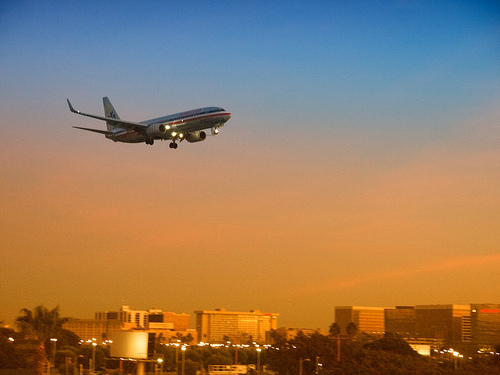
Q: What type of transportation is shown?
A: Airplane.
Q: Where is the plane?
A: In the sky.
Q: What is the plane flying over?
A: A city.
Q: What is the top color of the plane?
A: Blue.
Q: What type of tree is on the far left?
A: Palm tree.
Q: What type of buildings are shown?
A: Skyscrapers.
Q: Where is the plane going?
A: Up into the air.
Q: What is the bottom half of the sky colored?
A: Orange.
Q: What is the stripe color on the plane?
A: Red.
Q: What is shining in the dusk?
A: Street lights.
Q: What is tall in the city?
A: Buildings.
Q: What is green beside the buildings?
A: Trees.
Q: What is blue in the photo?
A: The sky.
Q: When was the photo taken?
A: Evening.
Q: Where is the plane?
A: In sky.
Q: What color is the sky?
A: Blue and orange.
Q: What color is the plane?
A: Grey.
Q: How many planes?
A: One.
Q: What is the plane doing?
A: Flying.